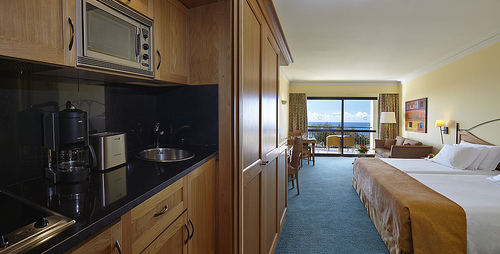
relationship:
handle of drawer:
[155, 202, 171, 218] [124, 179, 190, 243]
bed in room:
[353, 143, 500, 251] [0, 1, 499, 253]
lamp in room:
[380, 111, 397, 145] [0, 1, 499, 253]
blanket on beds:
[354, 155, 499, 253] [353, 143, 500, 251]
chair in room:
[287, 134, 301, 190] [0, 1, 499, 253]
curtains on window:
[289, 93, 309, 141] [304, 98, 378, 154]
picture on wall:
[404, 101, 428, 132] [280, 59, 500, 157]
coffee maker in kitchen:
[56, 105, 97, 182] [0, 1, 231, 252]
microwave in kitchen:
[78, 2, 155, 72] [0, 1, 231, 252]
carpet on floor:
[277, 154, 377, 253] [276, 152, 383, 252]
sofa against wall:
[375, 137, 429, 161] [280, 59, 500, 157]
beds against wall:
[353, 143, 500, 251] [280, 59, 500, 157]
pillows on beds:
[433, 139, 499, 175] [353, 143, 500, 251]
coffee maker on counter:
[56, 105, 97, 182] [1, 131, 200, 253]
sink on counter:
[137, 146, 194, 162] [1, 131, 200, 253]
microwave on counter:
[78, 2, 155, 72] [1, 131, 200, 253]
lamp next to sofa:
[380, 111, 397, 145] [375, 137, 429, 161]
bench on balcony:
[326, 134, 356, 151] [303, 126, 376, 157]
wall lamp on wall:
[435, 116, 451, 142] [280, 59, 500, 157]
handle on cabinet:
[154, 51, 163, 68] [152, 0, 190, 86]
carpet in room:
[277, 154, 377, 253] [0, 1, 499, 253]